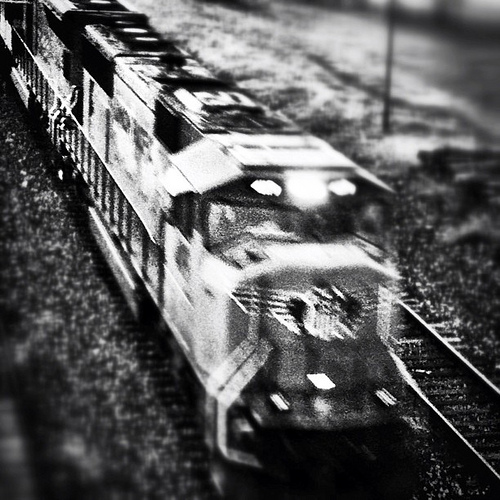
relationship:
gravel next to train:
[1, 103, 226, 498] [2, 155, 63, 390]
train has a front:
[6, 2, 399, 494] [215, 240, 398, 418]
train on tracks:
[6, 2, 399, 494] [399, 307, 498, 488]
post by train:
[386, 4, 388, 136] [197, 171, 401, 420]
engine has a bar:
[234, 238, 401, 393] [208, 345, 269, 467]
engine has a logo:
[208, 345, 269, 467] [301, 288, 348, 340]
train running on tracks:
[6, 2, 399, 494] [144, 358, 207, 497]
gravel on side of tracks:
[2, 155, 63, 390] [399, 307, 498, 488]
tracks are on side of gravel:
[399, 307, 498, 488] [1, 103, 226, 498]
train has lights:
[6, 2, 399, 494] [254, 179, 281, 198]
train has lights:
[6, 2, 399, 494] [331, 181, 354, 198]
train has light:
[6, 2, 399, 494] [291, 180, 327, 209]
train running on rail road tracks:
[6, 2, 399, 494] [144, 358, 207, 497]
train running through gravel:
[6, 2, 399, 494] [1, 103, 226, 498]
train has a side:
[6, 2, 399, 494] [80, 76, 151, 276]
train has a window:
[6, 2, 399, 494] [209, 200, 309, 245]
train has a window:
[6, 2, 399, 494] [306, 202, 384, 247]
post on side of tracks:
[386, 4, 388, 136] [399, 307, 498, 488]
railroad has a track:
[399, 307, 498, 488] [163, 370, 220, 493]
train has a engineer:
[6, 2, 399, 494] [349, 212, 370, 235]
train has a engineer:
[6, 2, 399, 494] [340, 207, 375, 239]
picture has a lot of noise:
[3, 4, 500, 499] [287, 46, 387, 157]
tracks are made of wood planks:
[399, 307, 498, 488] [409, 352, 453, 377]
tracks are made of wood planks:
[144, 358, 207, 497] [393, 326, 424, 337]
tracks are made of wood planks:
[399, 307, 498, 488] [399, 335, 431, 346]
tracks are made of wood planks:
[399, 307, 498, 488] [443, 400, 496, 410]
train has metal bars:
[6, 2, 399, 494] [51, 110, 64, 151]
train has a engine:
[6, 2, 399, 494] [234, 238, 401, 393]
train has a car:
[6, 2, 399, 494] [82, 26, 186, 172]